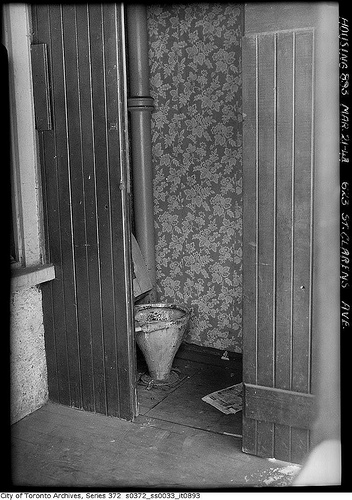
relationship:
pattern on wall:
[163, 117, 230, 291] [147, 0, 240, 350]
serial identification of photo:
[0, 494, 201, 498] [2, 4, 350, 489]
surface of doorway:
[245, 28, 323, 421] [119, 2, 261, 438]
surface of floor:
[60, 414, 187, 482] [17, 316, 276, 484]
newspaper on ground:
[201, 381, 243, 417] [12, 360, 335, 482]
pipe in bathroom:
[124, 2, 158, 303] [11, 9, 334, 480]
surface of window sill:
[14, 257, 55, 290] [11, 264, 62, 285]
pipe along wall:
[124, 2, 158, 303] [134, 11, 242, 363]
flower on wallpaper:
[179, 103, 217, 141] [147, 5, 242, 352]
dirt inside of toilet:
[135, 298, 196, 379] [132, 296, 193, 385]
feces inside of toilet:
[142, 311, 168, 325] [132, 296, 193, 385]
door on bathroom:
[30, 1, 140, 421] [45, 13, 320, 464]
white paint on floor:
[238, 455, 302, 483] [18, 401, 336, 481]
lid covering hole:
[133, 237, 154, 301] [144, 370, 181, 386]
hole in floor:
[144, 370, 181, 386] [18, 401, 336, 481]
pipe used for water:
[124, 2, 158, 303] [136, 168, 157, 298]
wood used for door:
[206, 28, 343, 410] [237, 7, 335, 467]